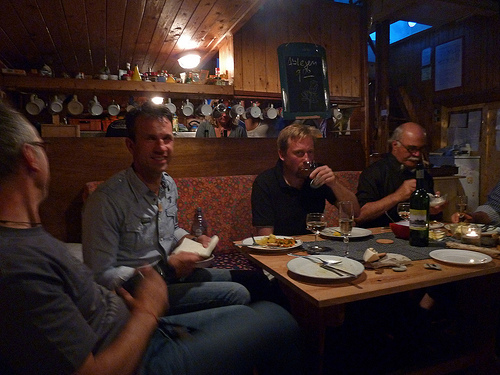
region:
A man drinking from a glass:
[234, 116, 361, 252]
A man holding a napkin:
[110, 104, 250, 316]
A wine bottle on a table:
[384, 156, 450, 258]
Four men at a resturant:
[10, 99, 449, 312]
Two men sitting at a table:
[258, 113, 445, 245]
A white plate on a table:
[276, 240, 376, 292]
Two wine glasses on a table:
[296, 197, 384, 263]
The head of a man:
[102, 87, 188, 185]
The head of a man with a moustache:
[375, 116, 455, 191]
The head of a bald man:
[364, 116, 440, 194]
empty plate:
[423, 239, 493, 279]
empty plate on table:
[418, 235, 495, 282]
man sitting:
[250, 118, 352, 261]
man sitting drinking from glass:
[247, 113, 361, 251]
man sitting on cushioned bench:
[250, 121, 357, 246]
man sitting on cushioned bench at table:
[249, 121, 356, 251]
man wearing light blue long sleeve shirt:
[74, 101, 224, 280]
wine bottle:
[402, 158, 436, 253]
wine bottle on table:
[392, 158, 460, 277]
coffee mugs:
[165, 89, 288, 127]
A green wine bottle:
[405, 157, 431, 252]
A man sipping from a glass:
[235, 116, 360, 231]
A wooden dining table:
[243, 217, 496, 364]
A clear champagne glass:
[330, 200, 369, 261]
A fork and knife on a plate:
[287, 255, 364, 277]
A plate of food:
[239, 234, 302, 255]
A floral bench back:
[85, 172, 442, 239]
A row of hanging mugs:
[25, 93, 293, 118]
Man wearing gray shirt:
[18, 238, 81, 319]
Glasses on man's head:
[21, 119, 66, 186]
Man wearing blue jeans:
[138, 300, 246, 358]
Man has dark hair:
[113, 98, 205, 157]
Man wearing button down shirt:
[113, 195, 190, 258]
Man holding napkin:
[163, 220, 222, 275]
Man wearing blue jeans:
[169, 187, 255, 305]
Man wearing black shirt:
[261, 135, 320, 245]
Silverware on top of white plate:
[283, 237, 360, 336]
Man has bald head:
[388, 104, 434, 193]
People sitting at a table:
[2, 114, 429, 309]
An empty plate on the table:
[284, 240, 358, 307]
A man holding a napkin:
[168, 227, 230, 277]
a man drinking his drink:
[262, 120, 345, 224]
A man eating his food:
[374, 108, 464, 243]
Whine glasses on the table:
[294, 187, 363, 274]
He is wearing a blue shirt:
[75, 171, 180, 291]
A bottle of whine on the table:
[399, 151, 446, 256]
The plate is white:
[428, 237, 489, 288]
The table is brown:
[236, 182, 488, 347]